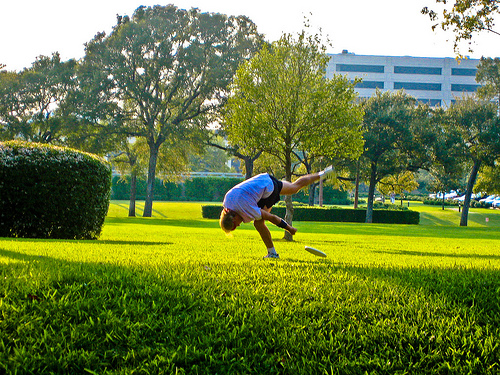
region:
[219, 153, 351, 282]
A man playing with a frisbee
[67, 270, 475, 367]
Green grass grows in the field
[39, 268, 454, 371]
The grass is cut short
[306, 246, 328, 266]
The frisbee is white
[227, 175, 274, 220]
The man wears a white shirt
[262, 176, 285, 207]
The man is wearing black shorts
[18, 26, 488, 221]
Green trees grow behind the man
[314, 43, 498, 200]
A building behind the trees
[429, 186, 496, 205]
Cars parked in front of the building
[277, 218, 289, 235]
A wristband on the man's arm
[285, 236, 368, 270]
frisbee is in the air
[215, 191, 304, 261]
person trying to catch frisbee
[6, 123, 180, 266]
shrub in the grass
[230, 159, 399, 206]
person's leg is in the air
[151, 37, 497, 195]
trees behind the person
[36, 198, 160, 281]
shadow of shrub in the grass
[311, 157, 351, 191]
person's sneakers are white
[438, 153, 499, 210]
vehicles in a parking lot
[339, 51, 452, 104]
windows long and narrow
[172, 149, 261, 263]
person's head close to the grass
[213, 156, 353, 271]
Person in field playing with frisbee.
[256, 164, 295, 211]
Person dressed in black shorts.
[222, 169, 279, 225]
Person dressed in white shirt.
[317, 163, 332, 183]
Person wearing white sock.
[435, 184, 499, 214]
Cars parked in parking spaces on side of field.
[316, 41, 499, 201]
Tall building rising at edge of field.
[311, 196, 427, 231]
Green shrub hedge running along field.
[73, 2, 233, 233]
Trees growing in field.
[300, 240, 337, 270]
White frisbee falling to ground.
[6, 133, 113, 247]
Huge shrub bush in middle of field.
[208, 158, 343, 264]
person playing with a Frisbee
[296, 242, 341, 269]
a Frisbee over the grass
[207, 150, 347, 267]
person has left feet raised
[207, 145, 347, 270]
person is bend forward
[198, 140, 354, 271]
person wears black short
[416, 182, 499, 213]
cars parked on parking lot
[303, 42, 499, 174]
a building behind trees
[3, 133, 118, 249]
bush nicely cutted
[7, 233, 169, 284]
shadows cast on green grass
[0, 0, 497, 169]
canopy of trees in a park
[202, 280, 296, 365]
the grass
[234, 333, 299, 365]
the grass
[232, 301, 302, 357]
the grass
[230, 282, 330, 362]
the grass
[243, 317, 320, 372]
the grass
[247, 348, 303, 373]
the grass